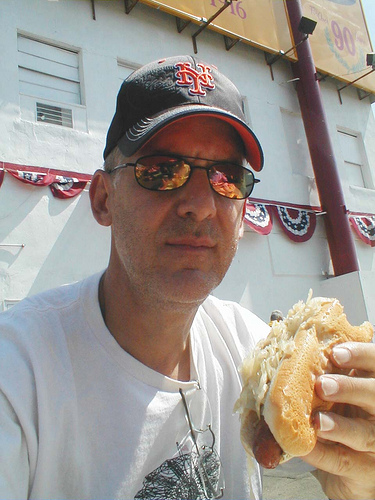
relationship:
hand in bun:
[296, 333, 362, 489] [238, 289, 353, 469]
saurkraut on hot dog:
[240, 285, 318, 404] [238, 288, 357, 468]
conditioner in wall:
[28, 91, 89, 129] [15, 45, 362, 305]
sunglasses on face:
[108, 154, 261, 200] [124, 122, 256, 305]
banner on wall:
[258, 196, 365, 253] [9, 53, 334, 358]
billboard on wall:
[143, 0, 375, 94] [15, 0, 374, 270]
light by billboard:
[289, 6, 321, 54] [166, 2, 370, 71]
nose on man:
[180, 177, 223, 215] [121, 82, 243, 309]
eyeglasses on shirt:
[178, 379, 224, 499] [16, 293, 274, 484]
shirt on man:
[16, 293, 274, 484] [44, 61, 277, 410]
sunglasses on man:
[99, 135, 252, 214] [74, 90, 296, 492]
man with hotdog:
[0, 55, 375, 500] [231, 282, 364, 485]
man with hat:
[34, 72, 294, 442] [91, 55, 268, 179]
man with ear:
[0, 55, 375, 500] [73, 164, 141, 230]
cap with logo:
[103, 55, 264, 172] [166, 53, 235, 114]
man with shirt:
[0, 55, 375, 500] [39, 265, 319, 477]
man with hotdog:
[0, 55, 375, 500] [230, 316, 356, 492]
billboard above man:
[190, 8, 372, 63] [26, 96, 253, 486]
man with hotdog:
[0, 55, 375, 500] [235, 304, 329, 453]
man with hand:
[0, 55, 375, 500] [327, 351, 368, 410]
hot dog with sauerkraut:
[238, 357, 321, 483] [233, 336, 301, 417]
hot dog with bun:
[253, 403, 287, 470] [258, 312, 349, 449]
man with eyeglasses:
[0, 55, 375, 500] [161, 374, 239, 481]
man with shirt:
[0, 55, 375, 500] [35, 270, 286, 496]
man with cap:
[0, 55, 375, 500] [121, 76, 267, 157]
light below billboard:
[298, 16, 317, 35] [143, 0, 375, 94]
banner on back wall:
[243, 197, 375, 247] [227, 96, 374, 323]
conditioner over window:
[36, 102, 73, 128] [17, 43, 107, 134]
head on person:
[109, 139, 243, 297] [9, 78, 261, 450]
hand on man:
[298, 342, 374, 500] [0, 55, 375, 500]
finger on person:
[327, 338, 374, 366] [2, 57, 369, 498]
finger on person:
[313, 375, 373, 412] [2, 57, 369, 498]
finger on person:
[313, 411, 375, 454] [2, 57, 369, 498]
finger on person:
[300, 439, 375, 481] [2, 57, 369, 498]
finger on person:
[328, 341, 375, 372] [2, 57, 369, 498]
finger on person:
[315, 374, 375, 418] [2, 57, 369, 498]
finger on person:
[311, 406, 373, 459] [2, 57, 369, 498]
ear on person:
[85, 167, 111, 229] [2, 57, 369, 498]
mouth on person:
[161, 233, 220, 257] [2, 57, 369, 498]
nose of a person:
[177, 165, 217, 222] [2, 57, 369, 498]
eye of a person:
[209, 162, 245, 200] [2, 57, 369, 498]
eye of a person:
[134, 158, 186, 190] [2, 57, 369, 498]